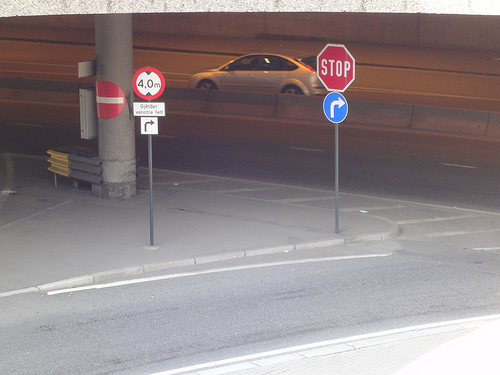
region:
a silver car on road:
[167, 44, 328, 112]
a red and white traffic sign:
[130, 62, 170, 102]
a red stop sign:
[315, 41, 362, 91]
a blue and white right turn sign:
[321, 87, 359, 134]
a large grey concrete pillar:
[91, 18, 135, 209]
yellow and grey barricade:
[35, 145, 107, 196]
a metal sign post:
[327, 125, 351, 236]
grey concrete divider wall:
[167, 88, 317, 129]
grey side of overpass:
[91, 1, 498, 12]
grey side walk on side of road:
[154, 324, 495, 374]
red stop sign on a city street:
[318, 43, 356, 90]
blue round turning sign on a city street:
[322, 91, 347, 124]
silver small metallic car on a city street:
[190, 51, 325, 98]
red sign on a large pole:
[94, 79, 124, 116]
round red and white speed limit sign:
[130, 68, 165, 101]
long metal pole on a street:
[145, 134, 155, 247]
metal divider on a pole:
[45, 149, 105, 194]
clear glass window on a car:
[221, 54, 298, 70]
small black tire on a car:
[194, 80, 216, 92]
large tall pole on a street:
[91, 11, 138, 198]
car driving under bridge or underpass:
[27, 35, 416, 227]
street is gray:
[117, 282, 299, 332]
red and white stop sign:
[315, 39, 355, 93]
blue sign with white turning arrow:
[313, 91, 354, 124]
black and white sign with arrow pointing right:
[138, 113, 161, 135]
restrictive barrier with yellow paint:
[35, 138, 103, 192]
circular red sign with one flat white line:
[88, 70, 131, 133]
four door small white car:
[188, 48, 319, 98]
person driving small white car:
[218, 45, 270, 78]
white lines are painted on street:
[46, 253, 397, 294]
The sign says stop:
[321, 51, 362, 96]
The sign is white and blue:
[317, 89, 355, 125]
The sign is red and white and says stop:
[309, 40, 361, 94]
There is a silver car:
[181, 43, 350, 111]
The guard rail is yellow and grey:
[43, 136, 105, 197]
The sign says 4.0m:
[129, 63, 167, 105]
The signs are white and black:
[128, 98, 176, 143]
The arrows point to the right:
[129, 92, 377, 162]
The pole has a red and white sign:
[86, 15, 154, 216]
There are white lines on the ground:
[155, 126, 499, 323]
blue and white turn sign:
[315, 88, 357, 127]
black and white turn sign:
[134, 115, 163, 138]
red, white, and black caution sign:
[131, 65, 172, 102]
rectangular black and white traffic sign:
[126, 97, 174, 118]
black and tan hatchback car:
[177, 43, 329, 113]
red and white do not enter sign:
[90, 75, 127, 124]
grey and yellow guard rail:
[41, 143, 108, 200]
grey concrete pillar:
[92, 12, 144, 193]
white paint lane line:
[427, 148, 485, 181]